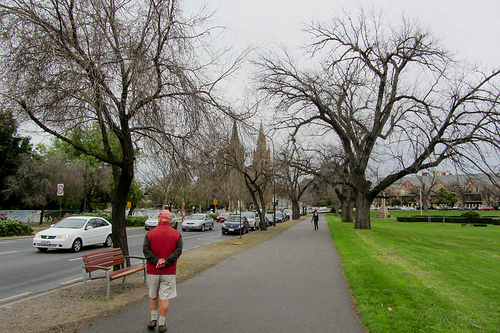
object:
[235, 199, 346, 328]
sidewalk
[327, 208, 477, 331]
field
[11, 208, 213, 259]
road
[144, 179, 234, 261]
car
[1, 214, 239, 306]
street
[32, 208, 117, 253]
car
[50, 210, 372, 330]
sidewalk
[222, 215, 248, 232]
car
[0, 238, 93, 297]
street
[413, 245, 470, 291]
grass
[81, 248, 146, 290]
red bench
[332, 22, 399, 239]
tree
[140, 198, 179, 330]
person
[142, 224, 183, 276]
red jacket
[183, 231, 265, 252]
street edge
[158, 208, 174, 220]
cap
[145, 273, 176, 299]
shorts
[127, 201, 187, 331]
man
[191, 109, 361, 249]
building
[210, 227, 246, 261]
grass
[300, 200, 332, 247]
sidewalk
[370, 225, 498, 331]
grass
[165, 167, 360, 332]
street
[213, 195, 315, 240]
car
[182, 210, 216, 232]
car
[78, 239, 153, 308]
bench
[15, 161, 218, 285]
road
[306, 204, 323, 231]
person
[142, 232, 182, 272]
vest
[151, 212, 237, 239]
car